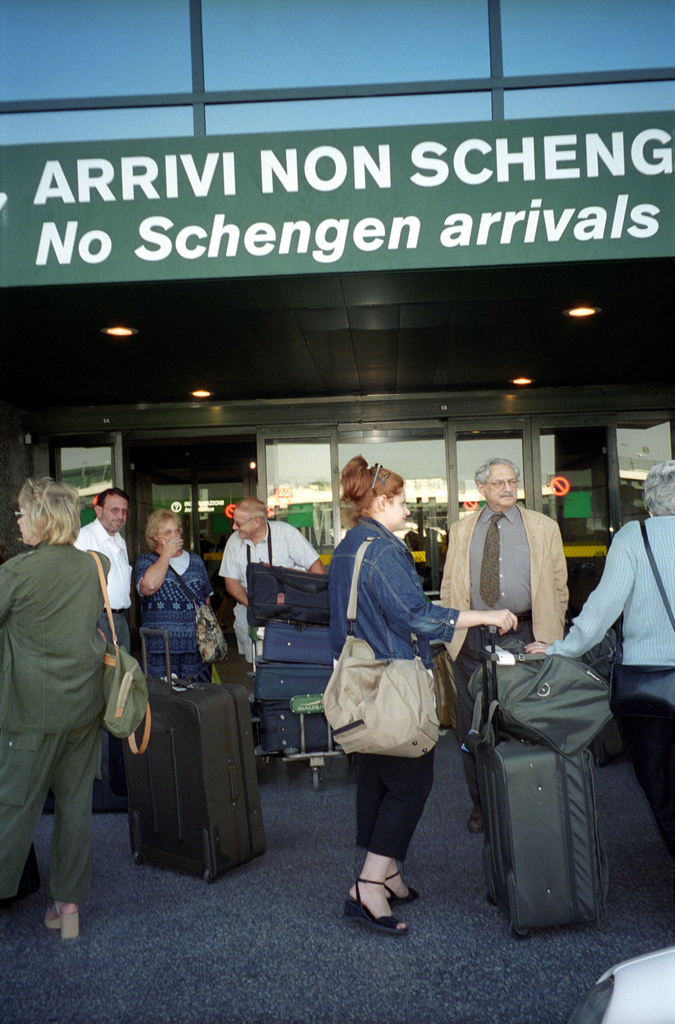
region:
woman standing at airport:
[132, 496, 205, 673]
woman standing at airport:
[321, 435, 419, 929]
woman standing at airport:
[614, 437, 674, 916]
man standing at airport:
[425, 451, 560, 766]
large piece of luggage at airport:
[119, 655, 262, 897]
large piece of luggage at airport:
[460, 732, 609, 923]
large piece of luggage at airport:
[249, 620, 335, 671]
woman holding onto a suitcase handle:
[320, 450, 614, 939]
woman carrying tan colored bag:
[310, 450, 523, 936]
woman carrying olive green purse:
[0, 471, 152, 939]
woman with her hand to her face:
[132, 505, 229, 688]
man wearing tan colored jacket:
[435, 454, 570, 832]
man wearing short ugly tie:
[433, 452, 573, 832]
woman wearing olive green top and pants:
[0, 473, 113, 940]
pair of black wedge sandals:
[336, 855, 421, 935]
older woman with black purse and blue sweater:
[525, 455, 673, 863]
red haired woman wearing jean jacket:
[313, 450, 520, 936]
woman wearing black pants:
[327, 712, 422, 856]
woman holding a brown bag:
[333, 545, 420, 793]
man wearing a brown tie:
[464, 503, 518, 604]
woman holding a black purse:
[580, 502, 674, 710]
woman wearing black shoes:
[316, 871, 426, 938]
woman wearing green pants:
[6, 697, 94, 923]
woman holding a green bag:
[81, 547, 160, 736]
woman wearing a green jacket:
[5, 548, 123, 737]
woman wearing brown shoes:
[33, 901, 89, 934]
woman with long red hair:
[322, 452, 515, 931]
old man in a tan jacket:
[440, 460, 564, 830]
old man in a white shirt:
[218, 499, 320, 664]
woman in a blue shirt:
[135, 509, 216, 683]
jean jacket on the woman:
[324, 521, 463, 672]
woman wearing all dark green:
[0, 477, 149, 939]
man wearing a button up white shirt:
[74, 483, 134, 804]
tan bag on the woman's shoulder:
[322, 530, 437, 757]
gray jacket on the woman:
[543, 517, 671, 672]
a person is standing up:
[1, 470, 113, 947]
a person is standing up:
[143, 506, 207, 681]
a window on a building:
[265, 435, 335, 543]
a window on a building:
[342, 427, 450, 597]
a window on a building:
[537, 425, 604, 536]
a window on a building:
[611, 411, 669, 515]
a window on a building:
[63, 443, 122, 514]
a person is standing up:
[336, 445, 519, 926]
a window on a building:
[47, 426, 108, 509]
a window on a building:
[196, 480, 247, 558]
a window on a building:
[264, 433, 332, 568]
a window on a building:
[342, 425, 447, 587]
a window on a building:
[462, 433, 527, 504]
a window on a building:
[530, 422, 609, 553]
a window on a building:
[620, 419, 674, 529]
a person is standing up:
[343, 440, 517, 937]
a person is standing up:
[437, 456, 582, 832]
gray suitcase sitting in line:
[471, 726, 635, 951]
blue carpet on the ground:
[195, 929, 316, 1010]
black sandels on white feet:
[312, 848, 433, 935]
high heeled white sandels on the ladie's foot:
[32, 891, 100, 936]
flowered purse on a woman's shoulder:
[182, 588, 230, 672]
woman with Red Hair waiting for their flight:
[317, 445, 474, 868]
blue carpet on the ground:
[432, 944, 479, 965]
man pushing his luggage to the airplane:
[204, 490, 342, 752]